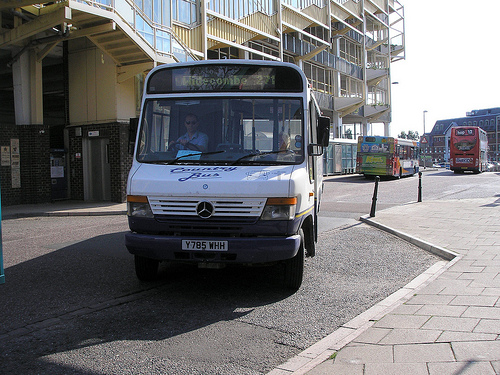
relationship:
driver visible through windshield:
[162, 108, 215, 153] [134, 96, 305, 161]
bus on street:
[115, 48, 332, 295] [3, 193, 500, 368]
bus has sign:
[115, 48, 332, 295] [192, 198, 217, 223]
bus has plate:
[115, 48, 332, 295] [177, 233, 233, 255]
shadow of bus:
[2, 229, 128, 372] [115, 48, 332, 295]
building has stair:
[3, 5, 412, 125] [46, 1, 198, 61]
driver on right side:
[162, 108, 215, 153] [144, 98, 218, 161]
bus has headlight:
[115, 48, 332, 295] [122, 193, 302, 224]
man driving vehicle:
[162, 108, 215, 153] [115, 48, 332, 295]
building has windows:
[3, 5, 412, 125] [142, 1, 387, 57]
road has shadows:
[3, 193, 500, 368] [2, 229, 128, 372]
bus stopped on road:
[115, 48, 332, 295] [7, 189, 453, 372]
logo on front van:
[192, 198, 217, 223] [115, 48, 332, 295]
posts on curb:
[368, 166, 428, 216] [361, 184, 499, 316]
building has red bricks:
[3, 5, 412, 125] [3, 117, 128, 199]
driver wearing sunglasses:
[162, 108, 215, 153] [181, 117, 202, 126]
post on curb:
[420, 107, 431, 135] [418, 160, 449, 170]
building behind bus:
[3, 5, 412, 125] [115, 48, 332, 295]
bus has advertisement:
[445, 120, 494, 178] [453, 139, 478, 153]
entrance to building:
[76, 131, 118, 204] [4, 1, 133, 198]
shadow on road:
[2, 229, 128, 372] [7, 189, 453, 372]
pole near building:
[420, 107, 431, 135] [3, 5, 412, 125]